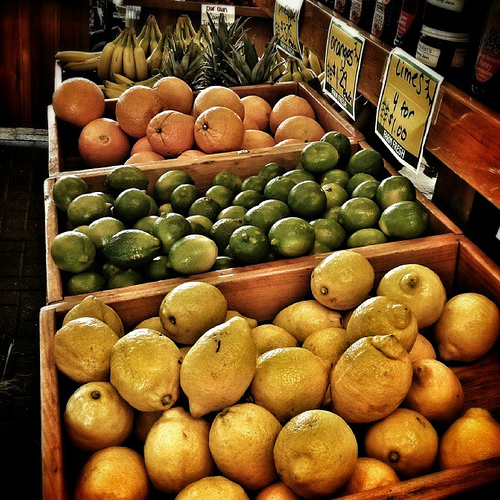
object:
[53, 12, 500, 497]
fruit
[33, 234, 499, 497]
bins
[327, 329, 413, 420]
lemons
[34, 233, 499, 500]
bin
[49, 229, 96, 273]
limes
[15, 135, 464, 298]
bin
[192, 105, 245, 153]
oranges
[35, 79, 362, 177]
bin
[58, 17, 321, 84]
tropical fruit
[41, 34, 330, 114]
bin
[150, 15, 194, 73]
bananas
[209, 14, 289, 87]
pineapples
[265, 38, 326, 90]
bananas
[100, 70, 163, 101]
bananas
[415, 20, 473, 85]
condiments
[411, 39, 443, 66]
label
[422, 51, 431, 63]
word 'jam'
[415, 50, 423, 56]
word fragm '…erry'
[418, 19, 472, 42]
lid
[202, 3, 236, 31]
sign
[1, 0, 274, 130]
back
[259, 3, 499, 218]
shelf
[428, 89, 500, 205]
scuffs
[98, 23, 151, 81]
bananas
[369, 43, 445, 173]
sign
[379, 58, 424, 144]
'limes 4 for $1.00'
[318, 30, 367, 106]
sign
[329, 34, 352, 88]
'oranges $1.29'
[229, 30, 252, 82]
leaves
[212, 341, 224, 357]
line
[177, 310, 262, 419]
lemon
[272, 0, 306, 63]
signs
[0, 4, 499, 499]
'farm fresh'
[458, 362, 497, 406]
bottom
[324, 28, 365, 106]
handwritten info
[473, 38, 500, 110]
honey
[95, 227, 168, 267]
lime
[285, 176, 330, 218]
lime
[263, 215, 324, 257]
lime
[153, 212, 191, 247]
lime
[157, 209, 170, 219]
bump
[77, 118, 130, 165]
orange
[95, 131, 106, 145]
navel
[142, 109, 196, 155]
orange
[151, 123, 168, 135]
stem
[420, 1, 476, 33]
jar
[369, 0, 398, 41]
jar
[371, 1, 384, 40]
sauce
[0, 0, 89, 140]
wall